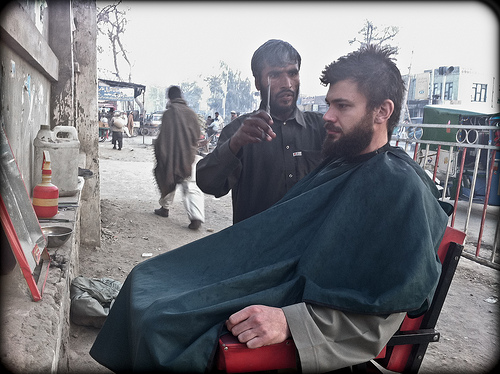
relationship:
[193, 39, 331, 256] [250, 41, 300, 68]
man cutting hair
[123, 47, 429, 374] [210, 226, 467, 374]
man sitting in chair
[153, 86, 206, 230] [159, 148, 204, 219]
man in pants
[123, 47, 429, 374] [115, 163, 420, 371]
man wearing cape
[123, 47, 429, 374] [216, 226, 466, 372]
man in chair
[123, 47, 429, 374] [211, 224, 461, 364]
man in chair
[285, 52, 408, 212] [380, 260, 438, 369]
man sitting in chair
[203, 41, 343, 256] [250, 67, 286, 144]
man with scissors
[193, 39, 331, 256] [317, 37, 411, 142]
man cutting hair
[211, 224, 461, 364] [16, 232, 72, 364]
chair near wall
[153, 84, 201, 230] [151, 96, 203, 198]
man wearing blanket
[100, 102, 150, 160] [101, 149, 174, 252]
person walking in street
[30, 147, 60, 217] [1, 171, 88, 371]
can on ledge